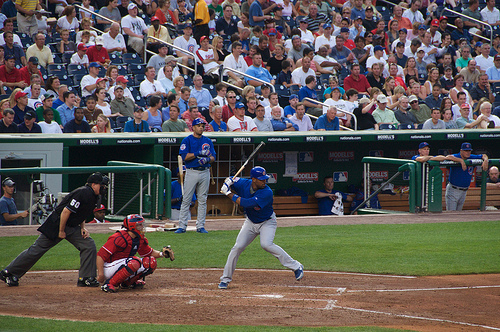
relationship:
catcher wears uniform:
[93, 210, 176, 293] [96, 228, 159, 288]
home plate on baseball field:
[249, 291, 285, 302] [1, 207, 499, 331]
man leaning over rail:
[444, 141, 490, 213] [425, 158, 499, 169]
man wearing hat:
[444, 141, 490, 213] [459, 139, 475, 155]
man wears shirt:
[444, 141, 490, 213] [448, 152, 486, 191]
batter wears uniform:
[218, 163, 307, 289] [218, 175, 304, 281]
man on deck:
[171, 116, 221, 235] [0, 210, 499, 242]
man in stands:
[267, 105, 300, 134] [0, 2, 498, 133]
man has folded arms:
[267, 105, 300, 134] [272, 122, 301, 133]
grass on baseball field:
[2, 220, 499, 277] [1, 207, 499, 331]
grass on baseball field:
[3, 310, 420, 331] [1, 207, 499, 331]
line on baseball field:
[345, 278, 499, 299] [1, 207, 499, 331]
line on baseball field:
[335, 303, 499, 330] [1, 207, 499, 331]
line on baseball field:
[257, 282, 346, 293] [1, 207, 499, 331]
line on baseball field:
[1, 308, 100, 324] [1, 207, 499, 331]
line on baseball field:
[4, 263, 419, 281] [1, 207, 499, 331]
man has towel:
[312, 175, 357, 216] [331, 191, 347, 217]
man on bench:
[312, 175, 357, 216] [250, 178, 499, 222]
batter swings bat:
[218, 163, 307, 289] [219, 139, 266, 197]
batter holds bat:
[218, 163, 307, 289] [219, 139, 266, 197]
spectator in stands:
[138, 62, 166, 98] [0, 2, 498, 133]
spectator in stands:
[342, 63, 374, 93] [0, 2, 498, 133]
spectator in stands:
[315, 105, 341, 131] [0, 2, 498, 133]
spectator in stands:
[367, 60, 385, 93] [0, 2, 498, 133]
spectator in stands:
[421, 105, 449, 131] [0, 2, 498, 133]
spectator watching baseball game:
[367, 60, 385, 93] [5, 106, 500, 330]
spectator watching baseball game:
[342, 63, 374, 93] [5, 106, 500, 330]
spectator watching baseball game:
[421, 105, 449, 131] [5, 106, 500, 330]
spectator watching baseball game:
[138, 62, 166, 98] [5, 106, 500, 330]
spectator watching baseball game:
[315, 105, 341, 131] [5, 106, 500, 330]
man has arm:
[444, 141, 490, 213] [472, 152, 492, 174]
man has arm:
[444, 141, 490, 213] [445, 152, 469, 172]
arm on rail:
[472, 152, 492, 174] [425, 158, 499, 169]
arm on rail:
[445, 152, 469, 172] [425, 158, 499, 169]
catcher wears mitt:
[93, 210, 176, 293] [160, 244, 175, 264]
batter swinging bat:
[218, 163, 307, 289] [219, 139, 266, 197]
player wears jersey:
[168, 168, 197, 221] [168, 176, 200, 209]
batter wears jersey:
[218, 163, 307, 289] [227, 175, 276, 224]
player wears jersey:
[351, 178, 384, 215] [349, 187, 381, 215]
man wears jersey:
[312, 175, 357, 216] [317, 187, 350, 217]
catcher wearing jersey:
[93, 210, 176, 293] [97, 227, 155, 263]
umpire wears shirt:
[2, 170, 113, 290] [34, 185, 102, 243]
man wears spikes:
[171, 116, 221, 235] [172, 227, 187, 235]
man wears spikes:
[171, 116, 221, 235] [197, 226, 209, 237]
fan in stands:
[122, 2, 148, 42] [0, 2, 498, 133]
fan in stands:
[86, 36, 113, 65] [0, 2, 498, 133]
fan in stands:
[386, 17, 400, 47] [0, 2, 498, 133]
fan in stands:
[171, 22, 200, 61] [0, 2, 498, 133]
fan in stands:
[146, 13, 173, 61] [0, 2, 498, 133]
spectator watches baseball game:
[138, 62, 166, 98] [5, 106, 500, 330]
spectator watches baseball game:
[342, 63, 374, 93] [5, 106, 500, 330]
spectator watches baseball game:
[367, 60, 385, 93] [5, 106, 500, 330]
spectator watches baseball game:
[421, 105, 449, 131] [5, 106, 500, 330]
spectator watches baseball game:
[315, 105, 341, 131] [5, 106, 500, 330]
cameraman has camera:
[2, 178, 38, 226] [27, 176, 65, 226]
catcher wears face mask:
[93, 210, 176, 293] [135, 213, 146, 238]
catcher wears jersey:
[93, 210, 176, 293] [97, 227, 155, 263]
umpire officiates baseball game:
[2, 170, 113, 290] [5, 106, 500, 330]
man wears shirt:
[8, 90, 38, 126] [9, 103, 36, 124]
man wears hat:
[8, 90, 38, 126] [13, 90, 30, 104]